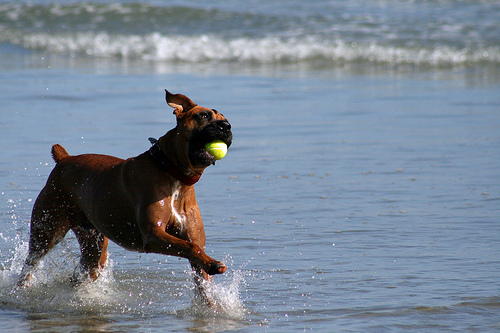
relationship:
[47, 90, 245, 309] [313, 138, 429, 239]
dog in water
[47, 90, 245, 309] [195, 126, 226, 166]
dog holds ball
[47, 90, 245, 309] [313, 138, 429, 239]
dog splashes water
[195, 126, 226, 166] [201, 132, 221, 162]
ball in mouth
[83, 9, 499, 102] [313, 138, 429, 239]
waves in water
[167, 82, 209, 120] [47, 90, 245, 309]
ear on dog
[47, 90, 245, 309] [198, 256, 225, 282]
dog has foot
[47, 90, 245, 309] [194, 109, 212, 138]
dog has eye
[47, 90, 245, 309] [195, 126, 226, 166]
dog has ball